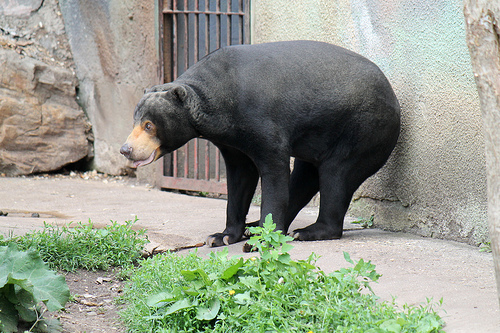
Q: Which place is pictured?
A: It is a zoo.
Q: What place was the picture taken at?
A: It was taken at the zoo.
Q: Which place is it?
A: It is a zoo.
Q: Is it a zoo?
A: Yes, it is a zoo.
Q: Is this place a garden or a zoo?
A: It is a zoo.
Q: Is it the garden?
A: No, it is the zoo.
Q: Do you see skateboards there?
A: No, there are no skateboards.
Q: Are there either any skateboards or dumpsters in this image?
A: No, there are no skateboards or dumpsters.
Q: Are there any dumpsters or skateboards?
A: No, there are no skateboards or dumpsters.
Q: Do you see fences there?
A: No, there are no fences.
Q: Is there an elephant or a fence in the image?
A: No, there are no fences or elephants.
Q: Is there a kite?
A: No, there are no kites.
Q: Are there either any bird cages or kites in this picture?
A: No, there are no kites or bird cages.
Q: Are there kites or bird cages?
A: No, there are no kites or bird cages.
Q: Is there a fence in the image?
A: No, there are no fences.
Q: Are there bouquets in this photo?
A: No, there are no bouquets.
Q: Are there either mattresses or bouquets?
A: No, there are no bouquets or mattresses.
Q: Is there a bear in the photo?
A: Yes, there is a bear.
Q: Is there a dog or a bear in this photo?
A: Yes, there is a bear.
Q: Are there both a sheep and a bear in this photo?
A: No, there is a bear but no sheep.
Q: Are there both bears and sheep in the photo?
A: No, there is a bear but no sheep.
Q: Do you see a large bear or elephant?
A: Yes, there is a large bear.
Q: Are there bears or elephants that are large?
A: Yes, the bear is large.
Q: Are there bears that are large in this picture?
A: Yes, there is a large bear.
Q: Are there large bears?
A: Yes, there is a large bear.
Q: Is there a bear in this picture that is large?
A: Yes, there is a bear that is large.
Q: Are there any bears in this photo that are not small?
A: Yes, there is a large bear.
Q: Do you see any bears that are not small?
A: Yes, there is a large bear.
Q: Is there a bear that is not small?
A: Yes, there is a large bear.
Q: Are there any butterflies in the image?
A: No, there are no butterflies.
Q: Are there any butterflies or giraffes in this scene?
A: No, there are no butterflies or giraffes.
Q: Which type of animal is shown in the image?
A: The animal is a bear.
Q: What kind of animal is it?
A: The animal is a bear.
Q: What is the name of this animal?
A: This is a bear.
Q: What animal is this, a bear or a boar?
A: This is a bear.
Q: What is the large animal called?
A: The animal is a bear.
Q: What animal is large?
A: The animal is a bear.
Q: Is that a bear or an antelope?
A: That is a bear.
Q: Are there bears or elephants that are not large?
A: No, there is a bear but it is large.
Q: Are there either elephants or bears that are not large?
A: No, there is a bear but it is large.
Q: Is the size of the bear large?
A: Yes, the bear is large.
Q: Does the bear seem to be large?
A: Yes, the bear is large.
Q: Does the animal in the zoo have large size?
A: Yes, the bear is large.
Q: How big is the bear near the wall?
A: The bear is large.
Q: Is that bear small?
A: No, the bear is large.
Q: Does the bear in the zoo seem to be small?
A: No, the bear is large.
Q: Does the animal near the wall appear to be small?
A: No, the bear is large.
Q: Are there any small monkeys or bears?
A: No, there is a bear but it is large.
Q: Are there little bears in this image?
A: No, there is a bear but it is large.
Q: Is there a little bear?
A: No, there is a bear but it is large.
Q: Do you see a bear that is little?
A: No, there is a bear but it is large.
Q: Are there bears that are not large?
A: No, there is a bear but it is large.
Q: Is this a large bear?
A: Yes, this is a large bear.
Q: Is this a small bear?
A: No, this is a large bear.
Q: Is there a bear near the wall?
A: Yes, there is a bear near the wall.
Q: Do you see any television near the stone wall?
A: No, there is a bear near the wall.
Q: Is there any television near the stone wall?
A: No, there is a bear near the wall.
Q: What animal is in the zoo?
A: The bear is in the zoo.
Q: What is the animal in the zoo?
A: The animal is a bear.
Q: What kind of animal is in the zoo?
A: The animal is a bear.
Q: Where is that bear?
A: The bear is in the zoo.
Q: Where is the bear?
A: The bear is in the zoo.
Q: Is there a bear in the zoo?
A: Yes, there is a bear in the zoo.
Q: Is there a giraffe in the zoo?
A: No, there is a bear in the zoo.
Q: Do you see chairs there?
A: No, there are no chairs.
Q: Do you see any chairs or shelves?
A: No, there are no chairs or shelves.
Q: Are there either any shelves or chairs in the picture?
A: No, there are no chairs or shelves.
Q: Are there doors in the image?
A: Yes, there is a door.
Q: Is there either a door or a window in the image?
A: Yes, there is a door.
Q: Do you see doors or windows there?
A: Yes, there is a door.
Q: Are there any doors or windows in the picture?
A: Yes, there is a door.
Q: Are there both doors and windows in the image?
A: No, there is a door but no windows.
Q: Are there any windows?
A: No, there are no windows.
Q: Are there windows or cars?
A: No, there are no windows or cars.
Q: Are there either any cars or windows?
A: No, there are no windows or cars.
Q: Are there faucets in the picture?
A: No, there are no faucets.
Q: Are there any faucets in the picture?
A: No, there are no faucets.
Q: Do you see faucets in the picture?
A: No, there are no faucets.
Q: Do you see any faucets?
A: No, there are no faucets.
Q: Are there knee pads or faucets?
A: No, there are no faucets or knee pads.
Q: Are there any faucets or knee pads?
A: No, there are no faucets or knee pads.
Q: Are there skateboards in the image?
A: No, there are no skateboards.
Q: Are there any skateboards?
A: No, there are no skateboards.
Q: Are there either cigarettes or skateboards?
A: No, there are no skateboards or cigarettes.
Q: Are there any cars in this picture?
A: No, there are no cars.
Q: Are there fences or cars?
A: No, there are no cars or fences.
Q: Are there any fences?
A: No, there are no fences.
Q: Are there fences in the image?
A: No, there are no fences.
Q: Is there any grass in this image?
A: Yes, there is grass.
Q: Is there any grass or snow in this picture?
A: Yes, there is grass.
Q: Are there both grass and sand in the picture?
A: No, there is grass but no sand.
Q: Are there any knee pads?
A: No, there are no knee pads.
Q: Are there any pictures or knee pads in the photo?
A: No, there are no knee pads or pictures.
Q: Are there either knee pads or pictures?
A: No, there are no knee pads or pictures.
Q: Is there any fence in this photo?
A: No, there are no fences.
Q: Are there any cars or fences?
A: No, there are no fences or cars.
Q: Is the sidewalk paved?
A: Yes, the sidewalk is paved.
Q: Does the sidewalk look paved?
A: Yes, the sidewalk is paved.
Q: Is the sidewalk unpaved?
A: No, the sidewalk is paved.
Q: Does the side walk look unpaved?
A: No, the side walk is paved.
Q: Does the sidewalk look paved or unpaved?
A: The sidewalk is paved.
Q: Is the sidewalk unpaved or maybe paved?
A: The sidewalk is paved.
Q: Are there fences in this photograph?
A: No, there are no fences.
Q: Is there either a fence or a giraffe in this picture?
A: No, there are no fences or giraffes.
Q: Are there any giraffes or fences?
A: No, there are no fences or giraffes.